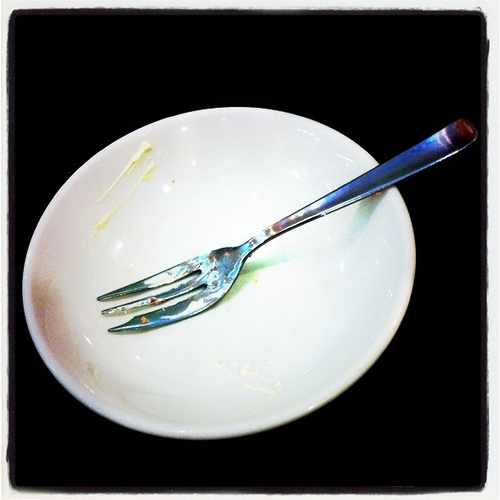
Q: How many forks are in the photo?
A: One.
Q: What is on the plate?
A: A fork.